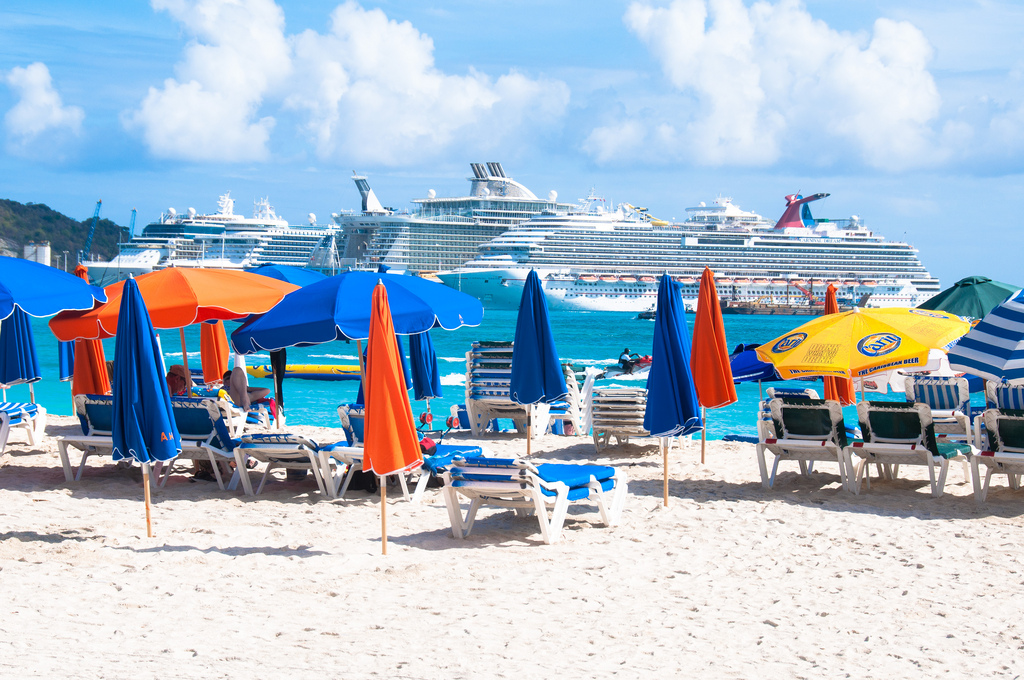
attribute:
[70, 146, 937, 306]
white ship — large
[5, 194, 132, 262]
small hill — green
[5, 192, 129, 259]
green hill — small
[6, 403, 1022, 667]
colored sand — white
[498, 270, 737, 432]
three umbrellas — open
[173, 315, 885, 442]
blue water — bright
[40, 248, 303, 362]
open umbrella — large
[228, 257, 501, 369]
large umbrella — open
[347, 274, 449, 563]
large umbrella — open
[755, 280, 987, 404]
open umbrella — large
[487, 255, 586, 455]
large umbrella — open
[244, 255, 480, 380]
open umbrella — large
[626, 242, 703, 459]
large umbrella — open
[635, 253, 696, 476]
umbrella — large, open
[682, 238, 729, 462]
umbrella — open, large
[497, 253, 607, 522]
umbrella — large, open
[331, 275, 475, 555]
umbrella — open, large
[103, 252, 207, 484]
umbrella — large, open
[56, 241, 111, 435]
umbrella — open, large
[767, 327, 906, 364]
symbols — blue